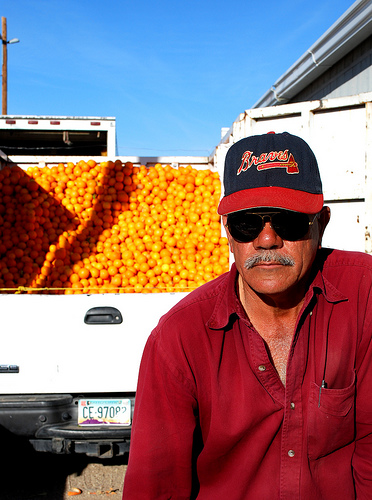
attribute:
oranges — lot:
[0, 156, 231, 294]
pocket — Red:
[302, 367, 356, 461]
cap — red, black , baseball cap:
[211, 100, 338, 259]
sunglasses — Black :
[222, 210, 313, 245]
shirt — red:
[180, 294, 307, 430]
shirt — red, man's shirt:
[122, 247, 370, 498]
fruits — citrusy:
[48, 193, 144, 291]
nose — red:
[253, 222, 281, 251]